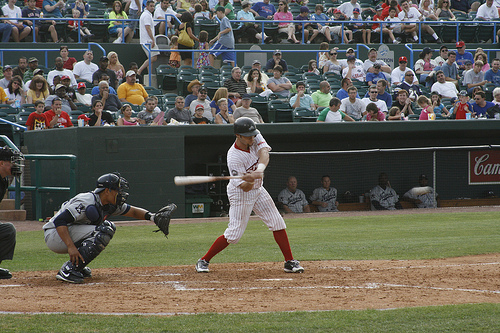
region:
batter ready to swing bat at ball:
[170, 111, 307, 278]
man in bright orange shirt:
[112, 61, 152, 108]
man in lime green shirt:
[305, 74, 336, 115]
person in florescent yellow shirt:
[105, 1, 129, 32]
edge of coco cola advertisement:
[462, 133, 497, 191]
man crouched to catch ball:
[35, 165, 179, 292]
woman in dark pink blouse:
[270, 1, 297, 28]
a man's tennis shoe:
[283, 256, 308, 273]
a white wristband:
[254, 163, 265, 173]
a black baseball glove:
[151, 198, 180, 235]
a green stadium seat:
[155, 63, 180, 92]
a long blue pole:
[148, 45, 351, 54]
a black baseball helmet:
[230, 116, 257, 136]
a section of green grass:
[282, 208, 497, 258]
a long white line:
[175, 278, 498, 295]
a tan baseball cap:
[126, 70, 139, 77]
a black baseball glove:
[156, 203, 176, 237]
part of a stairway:
[1, 193, 36, 222]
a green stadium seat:
[266, 95, 295, 122]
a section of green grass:
[261, 302, 498, 332]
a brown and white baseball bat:
[173, 173, 248, 184]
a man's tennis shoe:
[56, 266, 83, 285]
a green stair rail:
[3, 134, 83, 216]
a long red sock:
[272, 229, 294, 259]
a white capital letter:
[469, 146, 490, 177]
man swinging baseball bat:
[168, 114, 308, 279]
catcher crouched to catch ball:
[38, 167, 179, 289]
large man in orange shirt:
[115, 61, 150, 106]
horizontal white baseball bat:
[167, 165, 265, 195]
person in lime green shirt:
[308, 75, 336, 110]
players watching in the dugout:
[272, 157, 433, 215]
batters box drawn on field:
[168, 254, 430, 304]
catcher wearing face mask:
[94, 165, 136, 217]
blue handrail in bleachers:
[2, 13, 497, 64]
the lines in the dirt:
[143, 268, 418, 292]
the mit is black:
[152, 205, 185, 244]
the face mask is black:
[115, 177, 130, 207]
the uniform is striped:
[226, 140, 270, 235]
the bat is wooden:
[175, 175, 247, 184]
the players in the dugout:
[243, 156, 435, 213]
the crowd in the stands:
[62, 45, 459, 126]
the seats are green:
[164, 61, 231, 87]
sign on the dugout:
[450, 138, 497, 190]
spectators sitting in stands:
[4, 2, 497, 127]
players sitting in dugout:
[269, 129, 498, 214]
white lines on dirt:
[0, 254, 498, 314]